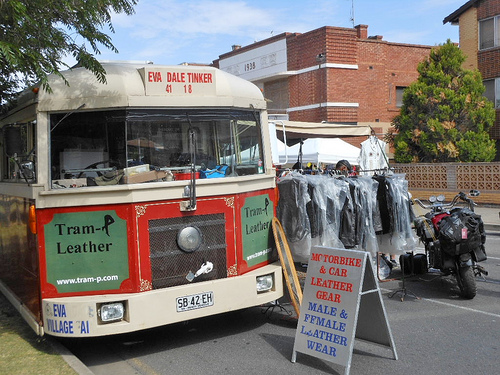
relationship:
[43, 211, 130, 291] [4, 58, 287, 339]
advertisments for bus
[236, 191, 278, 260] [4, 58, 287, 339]
advertisments for bus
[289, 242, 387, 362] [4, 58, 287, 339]
advertisments for bus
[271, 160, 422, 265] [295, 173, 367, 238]
clothes in plastic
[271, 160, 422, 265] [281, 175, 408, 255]
clothes in plastic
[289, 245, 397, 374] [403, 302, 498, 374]
advertisments on street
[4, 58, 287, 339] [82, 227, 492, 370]
bus on road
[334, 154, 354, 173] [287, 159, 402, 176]
head above rack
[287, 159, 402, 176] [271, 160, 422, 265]
rack of clothes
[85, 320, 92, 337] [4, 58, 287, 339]
blue letter on bus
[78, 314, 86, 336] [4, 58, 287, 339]
blue letter on bus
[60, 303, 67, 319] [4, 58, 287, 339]
blue letter on bus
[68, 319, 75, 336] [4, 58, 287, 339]
blue letter on bus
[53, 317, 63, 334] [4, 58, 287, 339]
blue letter on bus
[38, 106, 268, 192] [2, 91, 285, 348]
front window on bus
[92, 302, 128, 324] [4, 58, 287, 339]
headlight on bus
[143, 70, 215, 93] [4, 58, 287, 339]
text on bus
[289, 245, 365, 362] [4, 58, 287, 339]
text on bus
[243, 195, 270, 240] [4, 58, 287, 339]
text on bus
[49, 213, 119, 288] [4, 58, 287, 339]
text on bus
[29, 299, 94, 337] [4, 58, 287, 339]
text on bus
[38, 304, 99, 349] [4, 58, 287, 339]
print on bus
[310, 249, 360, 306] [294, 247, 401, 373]
print on sign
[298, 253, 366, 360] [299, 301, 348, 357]
text on blue text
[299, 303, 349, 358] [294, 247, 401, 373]
blue text on sign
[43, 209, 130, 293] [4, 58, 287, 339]
advertisments hanging on bus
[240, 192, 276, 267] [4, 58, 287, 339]
advertisments hanging on bus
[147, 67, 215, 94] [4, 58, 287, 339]
sign hanging on bus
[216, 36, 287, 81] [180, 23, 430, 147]
white sign in front of building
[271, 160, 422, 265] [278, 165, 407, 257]
clothes are on plastic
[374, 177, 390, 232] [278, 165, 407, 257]
clothes are on plastic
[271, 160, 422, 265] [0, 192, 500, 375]
clothes are on road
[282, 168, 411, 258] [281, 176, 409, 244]
bags wrapped around clothes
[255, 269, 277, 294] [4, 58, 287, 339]
light in front of bus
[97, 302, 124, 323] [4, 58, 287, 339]
headlight in front of bus